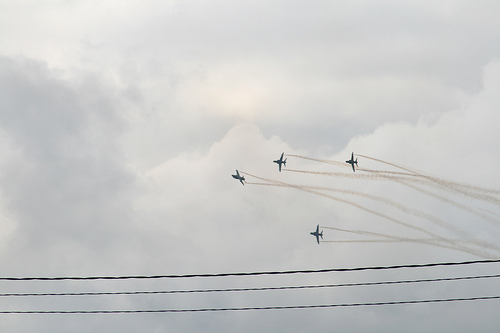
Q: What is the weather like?
A: It is cloudy.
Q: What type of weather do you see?
A: It is cloudy.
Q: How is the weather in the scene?
A: It is cloudy.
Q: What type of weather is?
A: It is cloudy.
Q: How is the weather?
A: It is cloudy.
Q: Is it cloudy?
A: Yes, it is cloudy.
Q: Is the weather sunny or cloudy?
A: It is cloudy.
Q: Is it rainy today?
A: No, it is cloudy.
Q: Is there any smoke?
A: Yes, there is smoke.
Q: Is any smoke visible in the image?
A: Yes, there is smoke.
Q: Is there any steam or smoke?
A: Yes, there is smoke.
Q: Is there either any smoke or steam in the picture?
A: Yes, there is smoke.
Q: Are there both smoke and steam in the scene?
A: No, there is smoke but no steam.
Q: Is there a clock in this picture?
A: No, there are no clocks.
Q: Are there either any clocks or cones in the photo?
A: No, there are no clocks or cones.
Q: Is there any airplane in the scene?
A: Yes, there is an airplane.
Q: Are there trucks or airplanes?
A: Yes, there is an airplane.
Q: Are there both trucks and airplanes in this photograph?
A: No, there is an airplane but no trucks.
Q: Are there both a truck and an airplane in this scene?
A: No, there is an airplane but no trucks.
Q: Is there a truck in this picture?
A: No, there are no trucks.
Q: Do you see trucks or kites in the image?
A: No, there are no trucks or kites.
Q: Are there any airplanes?
A: Yes, there is an airplane.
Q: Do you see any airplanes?
A: Yes, there is an airplane.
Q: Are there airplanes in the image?
A: Yes, there is an airplane.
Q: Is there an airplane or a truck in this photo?
A: Yes, there is an airplane.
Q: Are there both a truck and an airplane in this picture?
A: No, there is an airplane but no trucks.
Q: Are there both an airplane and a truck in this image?
A: No, there is an airplane but no trucks.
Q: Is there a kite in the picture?
A: No, there are no kites.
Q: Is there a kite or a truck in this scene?
A: No, there are no kites or trucks.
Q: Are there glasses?
A: No, there are no glasses.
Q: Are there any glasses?
A: No, there are no glasses.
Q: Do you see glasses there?
A: No, there are no glasses.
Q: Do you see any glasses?
A: No, there are no glasses.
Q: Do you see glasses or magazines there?
A: No, there are no glasses or magazines.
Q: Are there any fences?
A: No, there are no fences.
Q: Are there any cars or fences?
A: No, there are no fences or cars.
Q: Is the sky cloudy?
A: Yes, the sky is cloudy.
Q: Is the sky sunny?
A: No, the sky is cloudy.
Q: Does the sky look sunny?
A: No, the sky is cloudy.